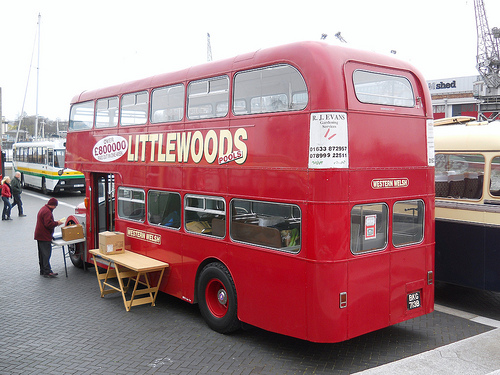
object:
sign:
[90, 134, 128, 163]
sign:
[306, 110, 351, 171]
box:
[98, 230, 126, 257]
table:
[86, 249, 168, 314]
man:
[34, 196, 65, 277]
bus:
[10, 140, 85, 197]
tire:
[194, 259, 244, 336]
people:
[1, 170, 29, 222]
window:
[231, 58, 309, 116]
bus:
[65, 41, 439, 344]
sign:
[363, 213, 378, 241]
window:
[349, 201, 390, 256]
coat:
[35, 205, 58, 243]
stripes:
[12, 166, 84, 181]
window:
[185, 74, 234, 122]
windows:
[349, 198, 428, 257]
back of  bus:
[320, 42, 438, 346]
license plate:
[405, 291, 423, 310]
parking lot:
[1, 169, 500, 374]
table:
[49, 231, 90, 280]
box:
[60, 223, 85, 242]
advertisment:
[125, 127, 249, 167]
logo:
[370, 177, 410, 190]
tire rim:
[204, 277, 228, 319]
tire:
[40, 179, 52, 196]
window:
[351, 66, 417, 110]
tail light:
[424, 269, 435, 288]